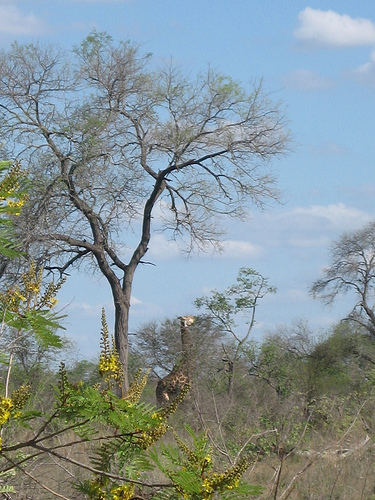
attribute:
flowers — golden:
[93, 305, 117, 390]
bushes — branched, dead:
[5, 388, 371, 495]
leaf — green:
[146, 447, 200, 493]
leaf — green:
[25, 307, 65, 349]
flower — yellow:
[96, 306, 124, 393]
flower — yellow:
[201, 450, 258, 496]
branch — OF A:
[137, 122, 206, 182]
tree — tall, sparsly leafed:
[1, 27, 294, 406]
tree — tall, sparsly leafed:
[306, 220, 374, 343]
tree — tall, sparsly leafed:
[193, 266, 276, 371]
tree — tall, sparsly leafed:
[0, 159, 251, 497]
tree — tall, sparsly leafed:
[260, 331, 347, 424]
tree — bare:
[309, 219, 373, 336]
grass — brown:
[268, 400, 301, 446]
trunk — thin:
[88, 260, 159, 373]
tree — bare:
[16, 44, 249, 268]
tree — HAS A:
[41, 172, 158, 396]